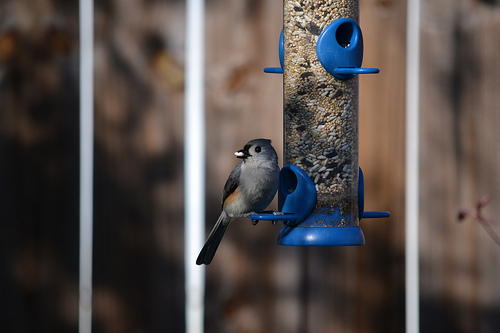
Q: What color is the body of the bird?
A: Grey.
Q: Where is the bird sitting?
A: On a bird feeder.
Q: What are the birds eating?
A: Bird seed.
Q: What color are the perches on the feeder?
A: Blue.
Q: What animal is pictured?
A: A bird.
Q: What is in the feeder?
A: Bird Seed.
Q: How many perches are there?
A: Four.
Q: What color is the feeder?
A: Blue.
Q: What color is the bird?
A: Gray.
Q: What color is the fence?
A: Brown.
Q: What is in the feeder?
A: Food.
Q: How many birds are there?
A: One.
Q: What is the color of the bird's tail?
A: Black.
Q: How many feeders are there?
A: One.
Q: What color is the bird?
A: Gray.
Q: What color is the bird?
A: Gray.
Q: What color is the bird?
A: Gray.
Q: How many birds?
A: 1.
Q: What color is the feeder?
A: Blue.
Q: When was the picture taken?
A: Daytime.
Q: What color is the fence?
A: White.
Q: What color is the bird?
A: Grey.